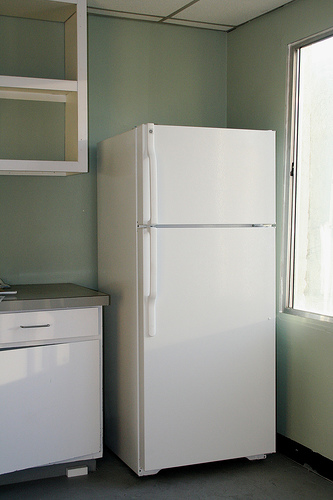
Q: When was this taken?
A: Daytime.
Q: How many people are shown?
A: 0.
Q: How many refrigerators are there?
A: 1.